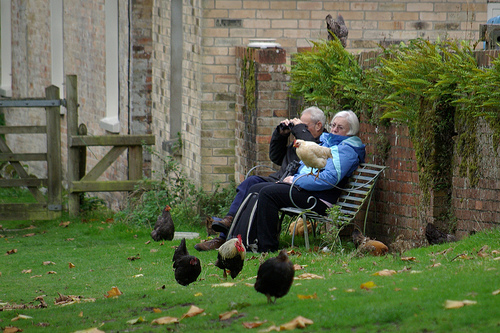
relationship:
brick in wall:
[413, 9, 454, 27] [197, 4, 498, 56]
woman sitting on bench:
[230, 108, 366, 254] [287, 170, 379, 246]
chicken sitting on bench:
[291, 137, 335, 179] [281, 160, 381, 257]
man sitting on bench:
[193, 106, 329, 252] [277, 153, 383, 246]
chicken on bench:
[291, 137, 335, 179] [263, 162, 387, 259]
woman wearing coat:
[230, 111, 361, 265] [295, 133, 364, 201]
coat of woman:
[295, 139, 369, 199] [224, 110, 374, 250]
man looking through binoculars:
[208, 108, 322, 234] [278, 118, 299, 132]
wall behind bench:
[289, 45, 500, 250] [244, 146, 388, 251]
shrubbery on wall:
[283, 40, 483, 121] [289, 45, 500, 250]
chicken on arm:
[294, 139, 337, 180] [291, 170, 383, 211]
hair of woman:
[335, 110, 360, 137] [224, 110, 374, 250]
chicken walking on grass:
[250, 247, 296, 304] [149, 267, 273, 329]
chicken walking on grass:
[215, 233, 250, 281] [37, 244, 225, 331]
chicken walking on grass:
[169, 236, 203, 291] [42, 236, 145, 331]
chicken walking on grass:
[147, 201, 178, 247] [21, 217, 153, 329]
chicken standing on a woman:
[291, 137, 335, 179] [230, 108, 366, 254]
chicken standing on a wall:
[321, 10, 351, 50] [208, 2, 443, 71]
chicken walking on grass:
[169, 236, 203, 291] [32, 235, 162, 331]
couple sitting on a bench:
[193, 105, 365, 252] [221, 159, 383, 258]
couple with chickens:
[193, 105, 365, 252] [289, 137, 391, 266]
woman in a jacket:
[230, 108, 366, 254] [293, 131, 367, 193]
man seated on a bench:
[193, 106, 329, 252] [233, 155, 387, 254]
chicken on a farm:
[254, 249, 296, 304] [0, 70, 481, 328]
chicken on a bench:
[291, 137, 335, 179] [233, 155, 387, 254]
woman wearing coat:
[230, 108, 366, 254] [292, 131, 365, 192]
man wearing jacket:
[193, 106, 329, 252] [267, 116, 327, 175]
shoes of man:
[195, 231, 232, 255] [264, 104, 328, 174]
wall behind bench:
[234, 35, 443, 249] [242, 153, 384, 257]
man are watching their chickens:
[193, 106, 329, 252] [168, 225, 295, 303]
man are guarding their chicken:
[193, 106, 329, 252] [254, 249, 296, 304]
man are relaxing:
[193, 106, 329, 252] [194, 100, 385, 249]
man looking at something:
[193, 106, 329, 252] [10, 14, 273, 304]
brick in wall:
[364, 11, 394, 21] [203, 3, 484, 210]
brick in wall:
[338, 10, 367, 20] [203, 3, 484, 210]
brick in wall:
[282, 10, 311, 21] [204, 5, 484, 234]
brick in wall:
[270, 17, 298, 34] [203, 3, 484, 210]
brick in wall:
[238, 18, 270, 31] [203, 3, 484, 210]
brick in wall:
[198, 28, 230, 39] [204, 5, 484, 234]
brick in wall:
[203, 63, 231, 78] [203, 3, 484, 210]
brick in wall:
[200, 155, 230, 167] [203, 3, 484, 210]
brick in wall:
[405, 3, 434, 13] [203, 3, 484, 210]